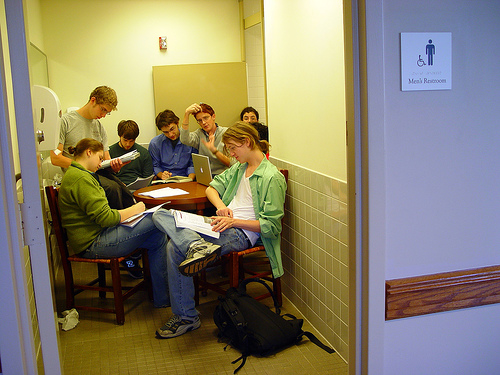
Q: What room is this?
A: It is a bathroom.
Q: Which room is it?
A: It is a bathroom.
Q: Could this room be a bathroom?
A: Yes, it is a bathroom.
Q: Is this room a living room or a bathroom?
A: It is a bathroom.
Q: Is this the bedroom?
A: No, it is the bathroom.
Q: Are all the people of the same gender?
A: No, they are both male and female.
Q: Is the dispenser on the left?
A: Yes, the dispenser is on the left of the image.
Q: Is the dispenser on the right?
A: No, the dispenser is on the left of the image.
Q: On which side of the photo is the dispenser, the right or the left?
A: The dispenser is on the left of the image.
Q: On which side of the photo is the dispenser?
A: The dispenser is on the left of the image.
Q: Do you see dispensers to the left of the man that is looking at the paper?
A: Yes, there is a dispenser to the left of the man.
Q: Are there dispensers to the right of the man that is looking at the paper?
A: No, the dispenser is to the left of the man.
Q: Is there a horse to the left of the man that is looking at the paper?
A: No, there is a dispenser to the left of the man.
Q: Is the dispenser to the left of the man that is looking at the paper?
A: Yes, the dispenser is to the left of the man.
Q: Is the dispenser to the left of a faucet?
A: No, the dispenser is to the left of the man.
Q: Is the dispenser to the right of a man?
A: No, the dispenser is to the left of a man.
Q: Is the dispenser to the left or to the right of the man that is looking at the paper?
A: The dispenser is to the left of the man.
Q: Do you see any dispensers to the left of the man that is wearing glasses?
A: Yes, there is a dispenser to the left of the man.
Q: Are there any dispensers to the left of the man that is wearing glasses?
A: Yes, there is a dispenser to the left of the man.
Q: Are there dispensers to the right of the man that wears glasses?
A: No, the dispenser is to the left of the man.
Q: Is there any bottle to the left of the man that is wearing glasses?
A: No, there is a dispenser to the left of the man.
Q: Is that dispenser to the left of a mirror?
A: No, the dispenser is to the left of a man.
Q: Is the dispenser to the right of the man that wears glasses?
A: No, the dispenser is to the left of the man.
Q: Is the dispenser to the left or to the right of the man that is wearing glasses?
A: The dispenser is to the left of the man.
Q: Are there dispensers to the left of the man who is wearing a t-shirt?
A: Yes, there is a dispenser to the left of the man.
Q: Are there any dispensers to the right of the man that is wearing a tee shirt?
A: No, the dispenser is to the left of the man.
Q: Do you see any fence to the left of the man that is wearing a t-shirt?
A: No, there is a dispenser to the left of the man.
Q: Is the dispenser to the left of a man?
A: Yes, the dispenser is to the left of a man.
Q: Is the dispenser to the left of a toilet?
A: No, the dispenser is to the left of a man.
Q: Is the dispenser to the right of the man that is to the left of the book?
A: No, the dispenser is to the left of the man.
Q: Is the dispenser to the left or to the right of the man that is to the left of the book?
A: The dispenser is to the left of the man.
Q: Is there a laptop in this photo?
A: Yes, there is a laptop.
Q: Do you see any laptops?
A: Yes, there is a laptop.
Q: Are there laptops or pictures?
A: Yes, there is a laptop.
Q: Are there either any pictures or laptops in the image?
A: Yes, there is a laptop.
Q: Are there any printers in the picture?
A: No, there are no printers.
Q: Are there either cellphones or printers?
A: No, there are no printers or cellphones.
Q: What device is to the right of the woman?
A: The device is a laptop.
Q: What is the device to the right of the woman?
A: The device is a laptop.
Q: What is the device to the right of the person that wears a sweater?
A: The device is a laptop.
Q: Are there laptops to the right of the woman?
A: Yes, there is a laptop to the right of the woman.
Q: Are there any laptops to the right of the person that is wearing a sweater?
A: Yes, there is a laptop to the right of the woman.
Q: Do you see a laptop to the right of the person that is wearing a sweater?
A: Yes, there is a laptop to the right of the woman.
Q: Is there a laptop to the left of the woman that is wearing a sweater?
A: No, the laptop is to the right of the woman.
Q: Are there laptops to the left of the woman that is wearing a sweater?
A: No, the laptop is to the right of the woman.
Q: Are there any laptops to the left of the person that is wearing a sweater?
A: No, the laptop is to the right of the woman.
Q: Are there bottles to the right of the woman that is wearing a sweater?
A: No, there is a laptop to the right of the woman.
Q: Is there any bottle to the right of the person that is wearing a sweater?
A: No, there is a laptop to the right of the woman.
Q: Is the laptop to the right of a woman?
A: Yes, the laptop is to the right of a woman.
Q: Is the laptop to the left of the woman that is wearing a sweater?
A: No, the laptop is to the right of the woman.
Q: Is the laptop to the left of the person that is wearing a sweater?
A: No, the laptop is to the right of the woman.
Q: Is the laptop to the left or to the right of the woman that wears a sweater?
A: The laptop is to the right of the woman.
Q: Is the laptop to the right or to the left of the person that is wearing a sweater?
A: The laptop is to the right of the woman.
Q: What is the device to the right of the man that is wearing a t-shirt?
A: The device is a laptop.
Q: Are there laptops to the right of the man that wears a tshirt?
A: Yes, there is a laptop to the right of the man.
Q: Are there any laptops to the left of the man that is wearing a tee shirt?
A: No, the laptop is to the right of the man.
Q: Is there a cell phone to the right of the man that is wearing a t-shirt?
A: No, there is a laptop to the right of the man.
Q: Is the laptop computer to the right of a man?
A: Yes, the laptop computer is to the right of a man.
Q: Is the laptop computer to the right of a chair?
A: No, the laptop computer is to the right of a man.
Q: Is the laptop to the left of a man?
A: No, the laptop is to the right of a man.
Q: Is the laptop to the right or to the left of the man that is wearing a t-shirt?
A: The laptop is to the right of the man.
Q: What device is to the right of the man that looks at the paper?
A: The device is a laptop.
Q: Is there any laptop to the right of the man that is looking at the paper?
A: Yes, there is a laptop to the right of the man.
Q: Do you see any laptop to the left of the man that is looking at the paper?
A: No, the laptop is to the right of the man.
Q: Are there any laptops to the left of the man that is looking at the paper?
A: No, the laptop is to the right of the man.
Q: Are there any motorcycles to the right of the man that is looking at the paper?
A: No, there is a laptop to the right of the man.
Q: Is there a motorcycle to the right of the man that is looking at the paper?
A: No, there is a laptop to the right of the man.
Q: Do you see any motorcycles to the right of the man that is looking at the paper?
A: No, there is a laptop to the right of the man.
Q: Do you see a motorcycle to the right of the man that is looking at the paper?
A: No, there is a laptop to the right of the man.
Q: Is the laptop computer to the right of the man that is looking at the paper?
A: Yes, the laptop computer is to the right of the man.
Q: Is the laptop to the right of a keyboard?
A: No, the laptop is to the right of the man.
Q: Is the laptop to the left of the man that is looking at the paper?
A: No, the laptop is to the right of the man.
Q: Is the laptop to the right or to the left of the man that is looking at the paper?
A: The laptop is to the right of the man.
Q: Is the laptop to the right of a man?
A: Yes, the laptop is to the right of a man.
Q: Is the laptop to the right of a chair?
A: No, the laptop is to the right of a man.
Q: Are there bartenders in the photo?
A: No, there are no bartenders.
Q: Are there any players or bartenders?
A: No, there are no bartenders or players.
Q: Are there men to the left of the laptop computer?
A: Yes, there is a man to the left of the laptop computer.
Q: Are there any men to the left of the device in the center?
A: Yes, there is a man to the left of the laptop computer.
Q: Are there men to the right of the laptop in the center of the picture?
A: No, the man is to the left of the laptop computer.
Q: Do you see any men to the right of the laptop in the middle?
A: No, the man is to the left of the laptop computer.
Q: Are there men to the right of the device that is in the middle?
A: No, the man is to the left of the laptop computer.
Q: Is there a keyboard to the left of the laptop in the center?
A: No, there is a man to the left of the laptop.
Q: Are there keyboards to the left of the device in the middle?
A: No, there is a man to the left of the laptop.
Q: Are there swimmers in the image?
A: No, there are no swimmers.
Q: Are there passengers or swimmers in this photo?
A: No, there are no swimmers or passengers.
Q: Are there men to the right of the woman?
A: Yes, there is a man to the right of the woman.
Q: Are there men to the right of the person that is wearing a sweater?
A: Yes, there is a man to the right of the woman.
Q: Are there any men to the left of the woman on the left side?
A: No, the man is to the right of the woman.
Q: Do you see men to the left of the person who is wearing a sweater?
A: No, the man is to the right of the woman.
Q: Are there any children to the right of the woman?
A: No, there is a man to the right of the woman.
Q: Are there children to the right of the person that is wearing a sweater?
A: No, there is a man to the right of the woman.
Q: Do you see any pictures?
A: No, there are no pictures.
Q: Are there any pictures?
A: No, there are no pictures.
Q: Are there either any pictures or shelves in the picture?
A: No, there are no pictures or shelves.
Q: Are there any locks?
A: No, there are no locks.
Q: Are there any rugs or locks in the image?
A: No, there are no locks or rugs.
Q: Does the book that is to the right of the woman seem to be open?
A: Yes, the book is open.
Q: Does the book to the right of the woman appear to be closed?
A: No, the book is open.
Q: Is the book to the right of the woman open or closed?
A: The book is open.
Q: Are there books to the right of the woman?
A: Yes, there is a book to the right of the woman.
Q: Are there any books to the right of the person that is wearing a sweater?
A: Yes, there is a book to the right of the woman.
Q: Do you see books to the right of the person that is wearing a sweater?
A: Yes, there is a book to the right of the woman.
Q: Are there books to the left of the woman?
A: No, the book is to the right of the woman.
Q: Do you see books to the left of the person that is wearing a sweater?
A: No, the book is to the right of the woman.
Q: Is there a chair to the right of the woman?
A: No, there is a book to the right of the woman.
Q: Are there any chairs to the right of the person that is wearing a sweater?
A: No, there is a book to the right of the woman.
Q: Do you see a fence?
A: No, there are no fences.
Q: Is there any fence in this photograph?
A: No, there are no fences.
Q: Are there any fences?
A: No, there are no fences.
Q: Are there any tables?
A: Yes, there is a table.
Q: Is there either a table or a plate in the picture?
A: Yes, there is a table.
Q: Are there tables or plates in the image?
A: Yes, there is a table.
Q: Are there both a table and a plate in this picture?
A: No, there is a table but no plates.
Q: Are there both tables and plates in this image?
A: No, there is a table but no plates.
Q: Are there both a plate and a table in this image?
A: No, there is a table but no plates.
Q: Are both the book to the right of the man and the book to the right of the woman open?
A: Yes, both the book and the book are open.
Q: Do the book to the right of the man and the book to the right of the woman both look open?
A: Yes, both the book and the book are open.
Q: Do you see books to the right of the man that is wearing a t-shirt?
A: Yes, there is a book to the right of the man.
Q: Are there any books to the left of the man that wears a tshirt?
A: No, the book is to the right of the man.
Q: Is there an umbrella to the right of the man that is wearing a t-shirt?
A: No, there is a book to the right of the man.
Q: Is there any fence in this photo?
A: No, there are no fences.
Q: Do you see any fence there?
A: No, there are no fences.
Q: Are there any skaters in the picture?
A: No, there are no skaters.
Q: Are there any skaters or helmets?
A: No, there are no skaters or helmets.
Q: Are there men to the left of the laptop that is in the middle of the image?
A: Yes, there is a man to the left of the laptop.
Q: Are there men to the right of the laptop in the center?
A: No, the man is to the left of the laptop computer.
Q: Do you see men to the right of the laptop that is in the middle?
A: No, the man is to the left of the laptop computer.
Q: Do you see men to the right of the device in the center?
A: No, the man is to the left of the laptop computer.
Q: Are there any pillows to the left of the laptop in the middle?
A: No, there is a man to the left of the laptop.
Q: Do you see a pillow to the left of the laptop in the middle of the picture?
A: No, there is a man to the left of the laptop.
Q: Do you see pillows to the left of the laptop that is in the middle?
A: No, there is a man to the left of the laptop.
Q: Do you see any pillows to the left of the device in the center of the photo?
A: No, there is a man to the left of the laptop.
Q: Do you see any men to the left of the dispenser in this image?
A: No, the man is to the right of the dispenser.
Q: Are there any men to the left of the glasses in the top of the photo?
A: Yes, there is a man to the left of the glasses.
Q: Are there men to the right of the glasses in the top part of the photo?
A: No, the man is to the left of the glasses.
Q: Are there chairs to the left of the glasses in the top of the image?
A: No, there is a man to the left of the glasses.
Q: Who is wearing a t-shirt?
A: The man is wearing a t-shirt.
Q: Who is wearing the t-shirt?
A: The man is wearing a t-shirt.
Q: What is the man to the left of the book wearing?
A: The man is wearing a tshirt.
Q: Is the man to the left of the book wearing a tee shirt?
A: Yes, the man is wearing a tee shirt.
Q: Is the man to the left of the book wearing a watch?
A: No, the man is wearing a tee shirt.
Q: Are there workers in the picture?
A: No, there are no workers.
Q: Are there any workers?
A: No, there are no workers.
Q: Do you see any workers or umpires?
A: No, there are no workers or umpires.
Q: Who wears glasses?
A: The man wears glasses.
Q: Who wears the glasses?
A: The man wears glasses.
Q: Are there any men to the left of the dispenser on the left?
A: No, the man is to the right of the dispenser.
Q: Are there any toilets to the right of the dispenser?
A: No, there is a man to the right of the dispenser.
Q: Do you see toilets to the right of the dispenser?
A: No, there is a man to the right of the dispenser.